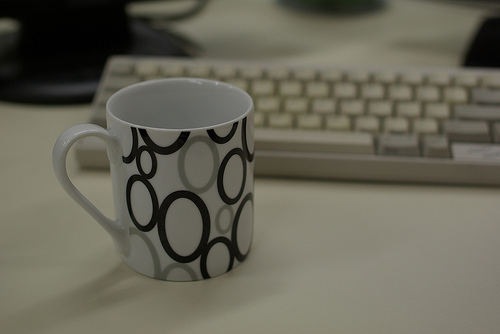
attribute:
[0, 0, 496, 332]
table — white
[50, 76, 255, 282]
mug — black, white, empty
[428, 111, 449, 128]
ground — white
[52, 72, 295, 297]
coffee mug — white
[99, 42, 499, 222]
keyboard — white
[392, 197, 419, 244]
ground — white, ceramic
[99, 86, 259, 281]
cup — empty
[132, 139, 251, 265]
circles — big, small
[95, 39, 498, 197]
keyboard — white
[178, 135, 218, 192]
circle — black, gray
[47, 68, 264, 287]
mug — empty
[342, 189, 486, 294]
table — white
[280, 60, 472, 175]
left hand — legacy model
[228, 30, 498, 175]
keyboard — plastic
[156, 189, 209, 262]
circle — black, grey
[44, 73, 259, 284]
cup — black, pop art, circle shaped, modern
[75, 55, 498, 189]
keyboard — white, blurry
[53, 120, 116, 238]
handle — white